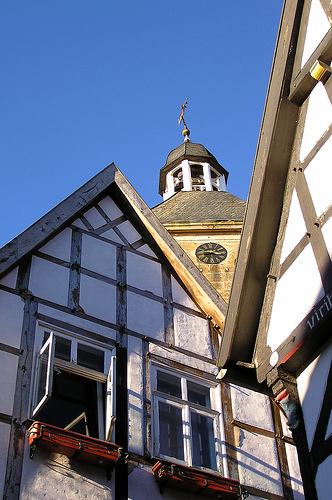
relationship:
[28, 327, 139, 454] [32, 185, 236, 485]
window on building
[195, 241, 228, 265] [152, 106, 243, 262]
clock on tower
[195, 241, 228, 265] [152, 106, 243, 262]
clock in tower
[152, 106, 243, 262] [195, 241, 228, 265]
tower has clock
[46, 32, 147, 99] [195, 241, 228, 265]
sky above clock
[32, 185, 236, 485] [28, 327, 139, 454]
building next to window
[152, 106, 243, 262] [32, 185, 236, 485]
tower near building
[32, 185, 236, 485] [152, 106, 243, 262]
building near tower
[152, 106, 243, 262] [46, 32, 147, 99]
tower in sky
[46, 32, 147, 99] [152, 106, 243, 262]
sky above tower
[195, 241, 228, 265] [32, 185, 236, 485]
clock near building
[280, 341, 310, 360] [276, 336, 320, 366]
paint on trimming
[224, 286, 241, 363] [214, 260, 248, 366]
paint on trimming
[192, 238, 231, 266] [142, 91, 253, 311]
clock on a building